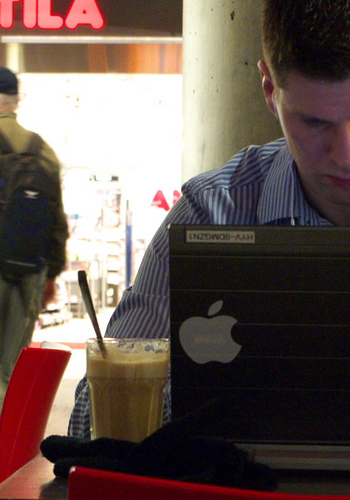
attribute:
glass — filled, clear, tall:
[80, 330, 169, 447]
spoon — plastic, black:
[73, 268, 121, 360]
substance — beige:
[83, 352, 170, 443]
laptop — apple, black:
[162, 217, 349, 482]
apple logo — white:
[175, 295, 248, 372]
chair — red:
[1, 341, 76, 487]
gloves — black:
[29, 417, 284, 495]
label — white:
[178, 227, 263, 252]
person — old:
[1, 65, 74, 418]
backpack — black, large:
[1, 120, 67, 291]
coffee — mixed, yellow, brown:
[86, 349, 172, 443]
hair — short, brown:
[256, 2, 349, 97]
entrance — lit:
[19, 72, 187, 346]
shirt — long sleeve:
[65, 133, 349, 444]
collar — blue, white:
[253, 140, 335, 229]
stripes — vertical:
[277, 165, 293, 207]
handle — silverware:
[73, 266, 118, 359]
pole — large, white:
[175, 0, 285, 196]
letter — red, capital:
[63, 2, 108, 33]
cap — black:
[1, 65, 24, 100]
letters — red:
[1, 3, 114, 35]